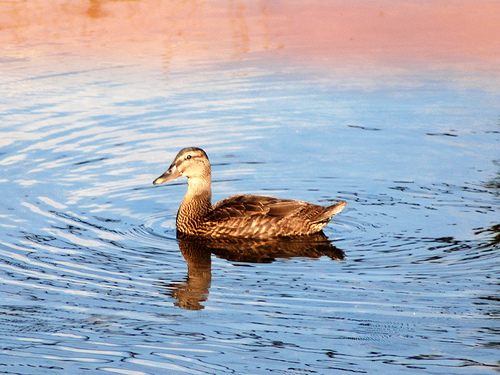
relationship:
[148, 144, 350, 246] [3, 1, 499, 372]
duck in water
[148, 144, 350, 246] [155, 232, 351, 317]
duck casts reflection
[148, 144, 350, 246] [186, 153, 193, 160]
duck has eye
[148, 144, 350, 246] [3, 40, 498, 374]
duck in body of water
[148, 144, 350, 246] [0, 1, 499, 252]
duck in daylight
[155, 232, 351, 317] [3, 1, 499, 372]
reflection in water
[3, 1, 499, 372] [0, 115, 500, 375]
water has whorl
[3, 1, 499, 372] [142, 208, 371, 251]
water has whorl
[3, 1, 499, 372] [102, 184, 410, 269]
water has whorl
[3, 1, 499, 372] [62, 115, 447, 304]
water has whorl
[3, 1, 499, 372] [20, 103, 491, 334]
water has whorl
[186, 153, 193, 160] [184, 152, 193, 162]
eye has rim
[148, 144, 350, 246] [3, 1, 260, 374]
duck faces left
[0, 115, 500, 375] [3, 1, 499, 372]
whorl in water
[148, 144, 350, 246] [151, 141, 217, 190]
duck has head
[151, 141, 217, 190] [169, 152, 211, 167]
head has stripe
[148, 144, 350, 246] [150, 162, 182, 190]
duck has beak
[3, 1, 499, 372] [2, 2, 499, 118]
water has odd hue effect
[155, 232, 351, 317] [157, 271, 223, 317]
reflection has distortion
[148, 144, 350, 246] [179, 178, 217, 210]
duck has neck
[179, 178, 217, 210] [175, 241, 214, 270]
neck has perfect reflection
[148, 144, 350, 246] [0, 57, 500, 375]
duck creating ripple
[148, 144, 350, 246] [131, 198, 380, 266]
duck stirs up ripple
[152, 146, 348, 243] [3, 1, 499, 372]
duck in water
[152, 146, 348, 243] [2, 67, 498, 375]
duck in pond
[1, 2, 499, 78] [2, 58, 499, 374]
pink merges into blue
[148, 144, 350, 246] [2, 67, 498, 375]
duck on pond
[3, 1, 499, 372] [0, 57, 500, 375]
water has ripple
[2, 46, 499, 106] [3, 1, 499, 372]
haze on water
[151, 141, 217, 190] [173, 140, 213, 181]
head has highlights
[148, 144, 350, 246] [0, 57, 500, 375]
duck causes ripple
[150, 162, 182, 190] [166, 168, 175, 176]
bill has nostril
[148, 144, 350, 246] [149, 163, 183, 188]
duck has bill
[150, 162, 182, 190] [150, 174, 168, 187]
beak reflects yellow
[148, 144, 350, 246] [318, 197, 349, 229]
duck has tail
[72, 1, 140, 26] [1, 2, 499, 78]
orange marks in pink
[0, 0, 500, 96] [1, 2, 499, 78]
orange marks in pink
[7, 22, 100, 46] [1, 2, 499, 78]
orange marks in pink